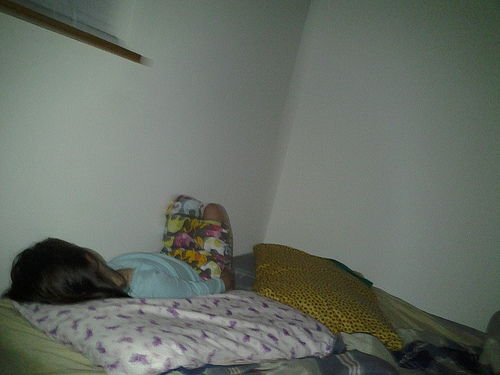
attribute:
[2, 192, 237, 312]
girl — little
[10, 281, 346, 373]
pillow — purple, white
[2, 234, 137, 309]
dark hair — large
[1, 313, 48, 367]
sheets — yellow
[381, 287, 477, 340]
sheets — yellow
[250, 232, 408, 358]
cushion — yellow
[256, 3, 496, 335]
wall — white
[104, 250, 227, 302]
shirt — blue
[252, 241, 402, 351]
pillow — yellow, black dots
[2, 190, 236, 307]
person — lying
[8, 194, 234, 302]
person — sleeping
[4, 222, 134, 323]
hair — black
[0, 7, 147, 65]
shelf — brown, wooden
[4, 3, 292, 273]
wall — white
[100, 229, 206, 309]
t-shirt — light blue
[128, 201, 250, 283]
pants — flowery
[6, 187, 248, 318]
girl — little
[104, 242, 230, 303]
t-shirt — light blue